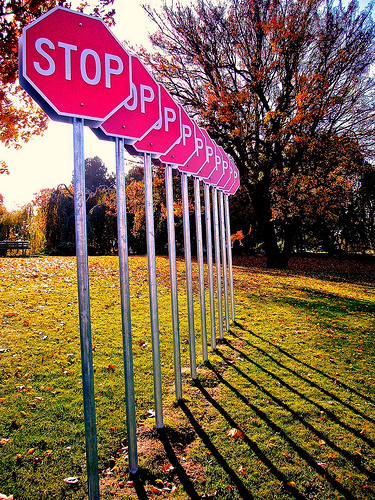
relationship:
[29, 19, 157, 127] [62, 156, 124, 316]
sign on pole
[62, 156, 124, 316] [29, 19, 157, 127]
pole on sign